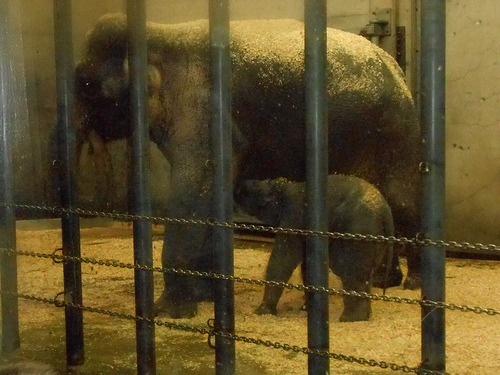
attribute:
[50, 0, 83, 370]
bar — big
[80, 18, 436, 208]
elephant — feeding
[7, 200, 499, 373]
chains — row, three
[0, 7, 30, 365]
metal post — large, grey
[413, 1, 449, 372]
post — large, gray, metal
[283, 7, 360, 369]
post — metal, large, gray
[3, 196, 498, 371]
fencing — dark, chain, wired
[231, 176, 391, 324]
baby elephant — nursing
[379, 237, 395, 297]
gray tail — skinny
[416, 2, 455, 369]
bar — five black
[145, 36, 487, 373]
metal post — large, gray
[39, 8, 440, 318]
elephant — eating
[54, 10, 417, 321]
elephant — gray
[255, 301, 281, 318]
foot — flat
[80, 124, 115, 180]
tusk — large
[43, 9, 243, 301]
elephant — adult